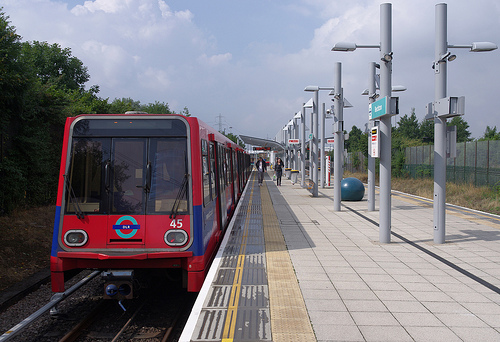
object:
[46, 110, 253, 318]
train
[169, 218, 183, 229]
45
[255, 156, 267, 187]
people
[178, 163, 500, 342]
platform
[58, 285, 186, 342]
tracks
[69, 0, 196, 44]
clouds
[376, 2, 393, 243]
post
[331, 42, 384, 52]
light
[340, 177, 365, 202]
ball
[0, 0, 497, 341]
day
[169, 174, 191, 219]
wipers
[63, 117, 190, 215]
windshield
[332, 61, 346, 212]
post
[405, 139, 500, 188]
fence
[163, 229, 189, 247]
headlight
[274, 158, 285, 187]
person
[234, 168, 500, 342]
sidewalk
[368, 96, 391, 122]
sign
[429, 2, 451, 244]
post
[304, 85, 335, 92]
light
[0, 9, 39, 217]
tree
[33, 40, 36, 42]
leaves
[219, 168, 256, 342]
line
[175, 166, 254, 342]
line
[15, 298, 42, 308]
gravel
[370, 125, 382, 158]
sign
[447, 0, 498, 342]
right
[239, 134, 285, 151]
shelter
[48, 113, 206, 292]
front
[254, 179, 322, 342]
stripe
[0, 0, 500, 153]
sky